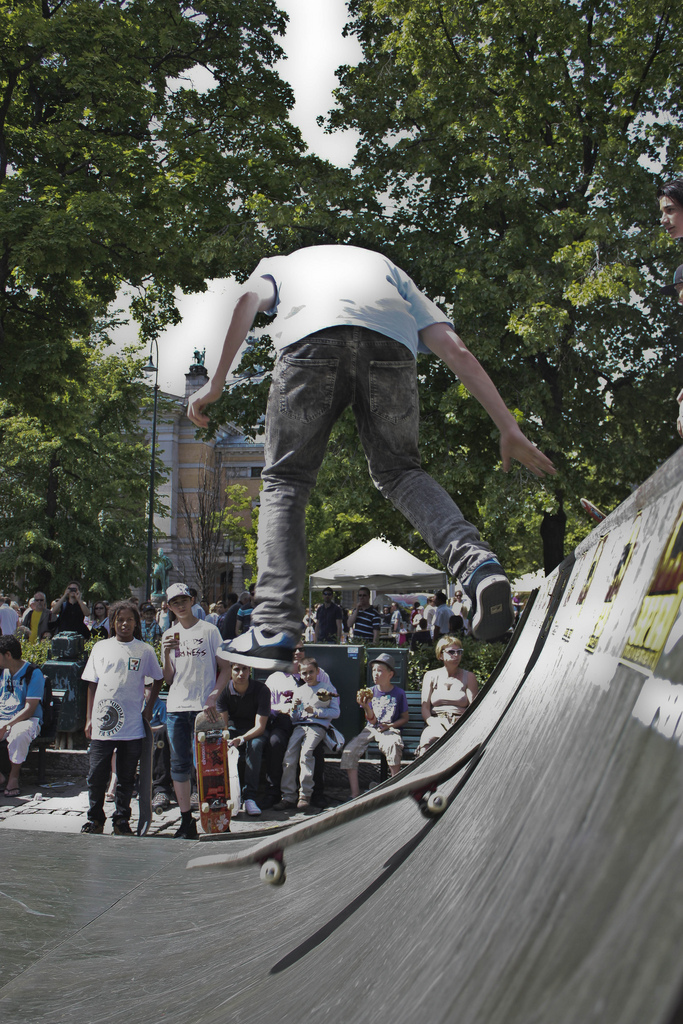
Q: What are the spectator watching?
A: The skateboarder.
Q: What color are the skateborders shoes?
A: Black.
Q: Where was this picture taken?
A: At a park.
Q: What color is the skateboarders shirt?
A: Blue.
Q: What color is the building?
A: Brown.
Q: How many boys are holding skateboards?
A: 2.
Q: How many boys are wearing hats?
A: 2.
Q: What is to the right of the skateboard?
A: Ramp.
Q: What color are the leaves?
A: Green.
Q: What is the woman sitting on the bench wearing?
A: Sunglasses.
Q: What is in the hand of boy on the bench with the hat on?
A: Sandwich.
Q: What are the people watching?
A: The skateboarder.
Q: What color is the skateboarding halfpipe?
A: Grey.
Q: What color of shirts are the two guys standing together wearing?
A: White.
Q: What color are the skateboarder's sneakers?
A: Black and white.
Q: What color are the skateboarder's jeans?
A: Black.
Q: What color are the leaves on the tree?
A: Green.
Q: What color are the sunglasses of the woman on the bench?
A: Black.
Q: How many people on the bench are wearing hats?
A: One.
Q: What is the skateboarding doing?
A: Skateboarding on ramp.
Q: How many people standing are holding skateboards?
A: Two.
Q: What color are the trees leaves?
A: Green.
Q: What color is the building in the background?
A: Yellow and white.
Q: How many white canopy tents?
A: One.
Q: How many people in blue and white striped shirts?
A: One.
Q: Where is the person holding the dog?
A: On bench.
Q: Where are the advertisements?
A: On ramp.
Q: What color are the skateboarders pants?
A: Gray.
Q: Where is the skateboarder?
A: Mid-air.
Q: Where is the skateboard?
A: Ramp.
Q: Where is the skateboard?
A: Halfpipe.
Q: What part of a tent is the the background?
A: Top.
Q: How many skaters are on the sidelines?
A: 2.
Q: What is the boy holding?
A: Skateboard.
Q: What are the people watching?
A: Skateboarder.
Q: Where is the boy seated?
A: Bench.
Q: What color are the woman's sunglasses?
A: Black.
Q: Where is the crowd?
A: Skatepark.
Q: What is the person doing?
A: Skateboarding.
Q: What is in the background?
A: Trees.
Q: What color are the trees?
A: Green.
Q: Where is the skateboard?
A: On the ramp.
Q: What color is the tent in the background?
A: White.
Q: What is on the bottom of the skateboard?
A: Wheels.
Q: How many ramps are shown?
A: One.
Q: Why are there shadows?
A: It is sunny.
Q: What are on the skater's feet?
A: Sneakers.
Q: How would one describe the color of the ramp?
A: Black.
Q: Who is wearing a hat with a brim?
A: Boy sitting on bench.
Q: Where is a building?
A: Between trees in background.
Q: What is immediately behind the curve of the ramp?
A: People on a bench.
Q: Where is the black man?
A: Next to boy holding skateboard.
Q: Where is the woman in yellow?
A: Left of the picture.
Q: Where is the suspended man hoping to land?
A: On skateboard.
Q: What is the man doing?
A: Skateboarding.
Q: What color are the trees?
A: Green.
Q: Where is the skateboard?
A: On the ramp.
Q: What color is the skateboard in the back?
A: Red.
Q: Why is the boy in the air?
A: He is doing a trick.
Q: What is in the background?
A: Buildings.